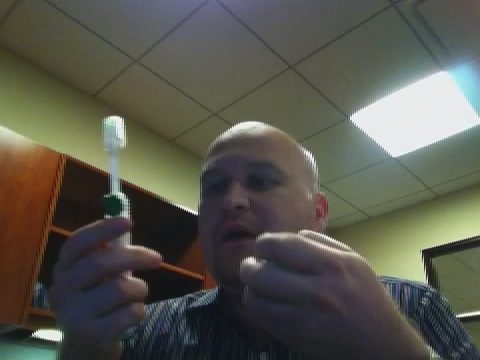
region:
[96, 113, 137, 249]
man holding a tooth brush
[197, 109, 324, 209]
Man with a bald head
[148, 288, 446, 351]
man wearing a stripped shirt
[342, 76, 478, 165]
light on the ceiling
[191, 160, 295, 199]
man looking at a tooth brush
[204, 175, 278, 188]
man with brown eyes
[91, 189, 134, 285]
man holding a white stick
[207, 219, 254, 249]
man with his mouth open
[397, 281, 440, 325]
man wearing a blue and gray shirt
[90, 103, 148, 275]
man holding on to a tooth brush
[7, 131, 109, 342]
the cabinet is brown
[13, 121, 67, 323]
the cabinet is brown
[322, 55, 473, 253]
a light on the ceiling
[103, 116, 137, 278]
A toothbrush in the man's right hand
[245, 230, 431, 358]
The left hand of the man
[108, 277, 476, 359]
The man is wearing a striped shirt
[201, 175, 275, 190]
The eyes of the man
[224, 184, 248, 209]
The nose of the man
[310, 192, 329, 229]
The left ear of the man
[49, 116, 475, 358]
A man looking at a toothbrush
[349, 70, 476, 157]
A light on the ceiling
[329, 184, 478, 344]
The wall behind the man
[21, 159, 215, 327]
A cabinet behind the man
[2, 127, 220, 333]
wood cabinet on wall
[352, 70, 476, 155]
light in ceiling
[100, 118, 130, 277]
white toothbrush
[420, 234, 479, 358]
door opening with black frame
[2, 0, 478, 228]
white ceiling tiles with black trim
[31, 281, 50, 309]
object sitting on wooden shelf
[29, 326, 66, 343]
light under wooden shelf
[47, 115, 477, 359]
man holding a white toothbrush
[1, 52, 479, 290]
beige walls in room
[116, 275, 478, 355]
striped dress shirt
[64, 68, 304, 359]
the man is looking at the toothbrush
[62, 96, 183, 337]
man is holding a toothbrush